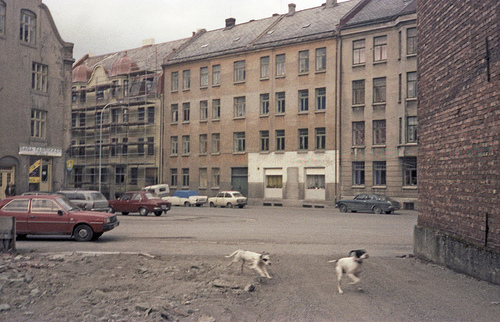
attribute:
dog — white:
[330, 249, 371, 296]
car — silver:
[57, 183, 110, 215]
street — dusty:
[170, 212, 404, 240]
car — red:
[7, 196, 114, 243]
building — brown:
[158, 10, 349, 214]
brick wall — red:
[412, 0, 495, 286]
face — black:
[340, 241, 377, 273]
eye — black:
[258, 257, 267, 272]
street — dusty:
[45, 223, 330, 299]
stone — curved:
[2, 1, 73, 190]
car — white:
[163, 185, 208, 206]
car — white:
[207, 187, 247, 208]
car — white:
[140, 180, 170, 198]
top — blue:
[170, 187, 198, 197]